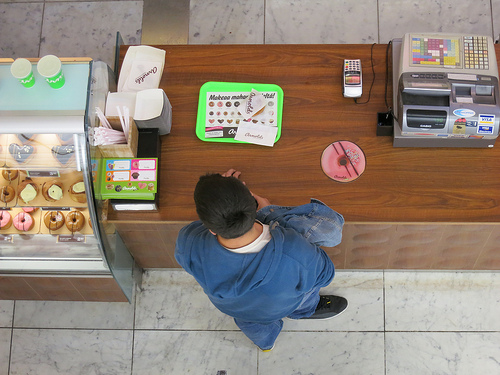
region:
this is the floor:
[251, 5, 316, 30]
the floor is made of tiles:
[376, 295, 464, 340]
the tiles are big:
[371, 280, 440, 336]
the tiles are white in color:
[372, 288, 471, 374]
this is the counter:
[181, 41, 296, 171]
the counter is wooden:
[294, 57, 319, 97]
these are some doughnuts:
[2, 179, 79, 234]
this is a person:
[165, 134, 365, 351]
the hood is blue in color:
[233, 260, 271, 301]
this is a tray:
[194, 78, 289, 147]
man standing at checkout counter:
[175, 166, 350, 352]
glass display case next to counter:
[0, 52, 135, 302]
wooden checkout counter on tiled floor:
[101, 41, 496, 271]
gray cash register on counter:
[387, 30, 494, 147]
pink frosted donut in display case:
[10, 210, 30, 230]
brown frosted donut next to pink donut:
[40, 210, 60, 230]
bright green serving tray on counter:
[195, 80, 280, 142]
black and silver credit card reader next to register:
[340, 55, 360, 96]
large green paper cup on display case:
[35, 51, 65, 86]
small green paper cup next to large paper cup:
[10, 55, 33, 85]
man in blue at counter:
[162, 150, 324, 343]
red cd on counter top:
[309, 140, 374, 187]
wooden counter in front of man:
[128, 37, 497, 217]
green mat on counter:
[178, 75, 294, 144]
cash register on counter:
[376, 7, 496, 157]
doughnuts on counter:
[10, 191, 117, 263]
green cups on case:
[6, 49, 76, 101]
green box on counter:
[98, 150, 175, 211]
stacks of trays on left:
[101, 70, 176, 130]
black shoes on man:
[299, 287, 335, 311]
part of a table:
[290, 143, 323, 177]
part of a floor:
[390, 305, 417, 346]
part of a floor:
[347, 270, 384, 319]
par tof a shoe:
[319, 290, 345, 325]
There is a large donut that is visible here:
[317, 130, 367, 196]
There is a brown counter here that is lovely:
[407, 170, 435, 202]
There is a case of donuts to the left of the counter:
[17, 160, 65, 273]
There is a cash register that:
[404, 89, 495, 147]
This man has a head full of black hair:
[195, 174, 240, 231]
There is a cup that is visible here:
[41, 65, 63, 98]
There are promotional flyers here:
[106, 147, 166, 212]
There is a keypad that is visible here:
[338, 56, 372, 105]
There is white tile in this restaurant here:
[403, 295, 443, 352]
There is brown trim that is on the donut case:
[71, 274, 104, 298]